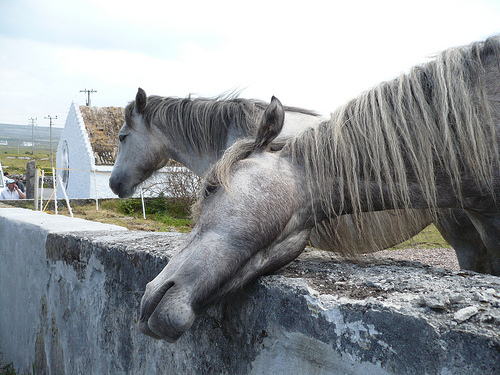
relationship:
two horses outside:
[109, 30, 496, 343] [0, 8, 49, 156]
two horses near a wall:
[109, 30, 496, 343] [15, 221, 89, 363]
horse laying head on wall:
[142, 100, 323, 343] [15, 221, 89, 363]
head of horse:
[142, 100, 323, 343] [108, 86, 199, 198]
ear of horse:
[254, 94, 286, 156] [108, 86, 199, 198]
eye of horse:
[117, 129, 130, 144] [108, 86, 199, 198]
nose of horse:
[111, 174, 122, 193] [108, 86, 199, 198]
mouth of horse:
[144, 277, 180, 330] [108, 86, 199, 198]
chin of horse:
[161, 305, 190, 339] [108, 86, 199, 198]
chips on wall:
[433, 292, 479, 330] [15, 221, 89, 363]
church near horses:
[57, 103, 109, 201] [109, 30, 496, 343]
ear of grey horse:
[254, 94, 286, 156] [108, 86, 199, 198]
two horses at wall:
[109, 30, 496, 343] [15, 221, 89, 363]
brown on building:
[93, 110, 113, 156] [57, 103, 109, 201]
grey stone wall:
[7, 241, 39, 280] [15, 221, 89, 363]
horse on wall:
[108, 86, 199, 198] [15, 221, 89, 363]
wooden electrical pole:
[50, 121, 55, 180] [30, 110, 38, 163]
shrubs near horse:
[161, 172, 189, 216] [108, 86, 199, 198]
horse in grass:
[108, 86, 199, 198] [157, 212, 181, 224]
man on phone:
[0, 179, 25, 202] [13, 181, 17, 187]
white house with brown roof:
[72, 153, 89, 173] [87, 111, 112, 135]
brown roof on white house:
[93, 110, 113, 156] [57, 103, 109, 201]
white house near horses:
[72, 153, 89, 173] [109, 30, 496, 343]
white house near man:
[72, 153, 89, 173] [0, 179, 25, 202]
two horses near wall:
[109, 30, 496, 343] [15, 221, 89, 363]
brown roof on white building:
[93, 110, 113, 156] [72, 104, 102, 199]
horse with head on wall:
[108, 86, 199, 198] [15, 221, 89, 363]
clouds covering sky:
[239, 6, 295, 59] [78, 13, 131, 53]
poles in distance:
[26, 115, 57, 145] [4, 98, 58, 171]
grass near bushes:
[157, 212, 181, 224] [122, 199, 163, 212]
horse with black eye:
[108, 86, 199, 198] [117, 129, 130, 144]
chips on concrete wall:
[433, 292, 479, 330] [15, 221, 89, 363]